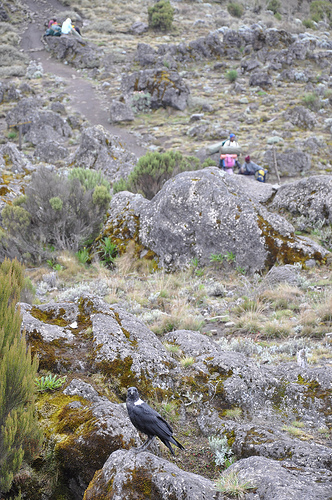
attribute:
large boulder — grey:
[28, 161, 116, 240]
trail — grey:
[88, 110, 141, 152]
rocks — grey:
[227, 206, 293, 254]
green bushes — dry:
[69, 175, 109, 207]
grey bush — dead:
[239, 290, 275, 324]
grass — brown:
[59, 290, 136, 345]